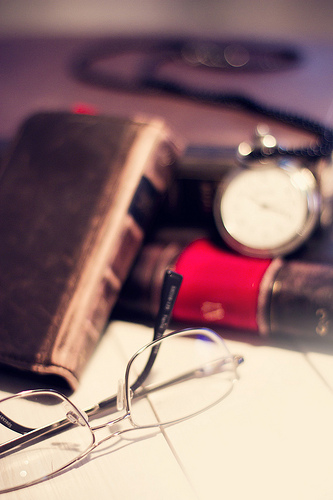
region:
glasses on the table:
[40, 244, 330, 479]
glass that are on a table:
[14, 269, 331, 452]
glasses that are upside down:
[10, 297, 318, 431]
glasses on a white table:
[14, 274, 325, 456]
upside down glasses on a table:
[6, 274, 300, 476]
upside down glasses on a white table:
[22, 260, 259, 489]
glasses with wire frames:
[10, 280, 302, 477]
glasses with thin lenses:
[26, 277, 284, 480]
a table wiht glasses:
[22, 235, 328, 466]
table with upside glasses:
[18, 259, 289, 490]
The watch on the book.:
[225, 161, 310, 249]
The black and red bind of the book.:
[133, 238, 331, 339]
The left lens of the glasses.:
[2, 387, 90, 475]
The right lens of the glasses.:
[113, 341, 228, 411]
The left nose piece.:
[62, 403, 85, 427]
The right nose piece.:
[107, 377, 127, 407]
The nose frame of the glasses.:
[97, 413, 131, 439]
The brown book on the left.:
[8, 99, 139, 353]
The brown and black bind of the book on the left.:
[42, 141, 165, 388]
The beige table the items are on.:
[20, 326, 318, 498]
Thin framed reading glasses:
[0, 272, 247, 491]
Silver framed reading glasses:
[0, 270, 246, 497]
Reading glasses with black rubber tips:
[0, 270, 247, 491]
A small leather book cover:
[3, 107, 187, 391]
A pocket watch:
[210, 155, 317, 250]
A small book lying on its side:
[117, 238, 327, 336]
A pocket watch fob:
[67, 33, 330, 158]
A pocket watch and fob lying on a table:
[70, 32, 328, 256]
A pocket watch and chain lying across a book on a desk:
[77, 30, 331, 258]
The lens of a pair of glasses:
[124, 329, 240, 423]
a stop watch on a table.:
[192, 121, 331, 264]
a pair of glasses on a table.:
[1, 300, 257, 497]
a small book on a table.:
[1, 104, 190, 421]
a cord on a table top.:
[67, 30, 331, 142]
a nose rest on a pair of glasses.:
[110, 375, 127, 416]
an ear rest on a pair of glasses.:
[94, 264, 188, 409]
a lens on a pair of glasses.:
[125, 320, 233, 427]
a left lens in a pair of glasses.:
[0, 380, 89, 494]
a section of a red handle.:
[137, 225, 293, 344]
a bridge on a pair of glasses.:
[92, 406, 131, 446]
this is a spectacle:
[86, 345, 202, 420]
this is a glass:
[150, 358, 206, 396]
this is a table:
[254, 377, 322, 471]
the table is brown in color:
[245, 435, 311, 479]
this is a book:
[30, 125, 116, 283]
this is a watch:
[226, 159, 302, 232]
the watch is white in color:
[237, 206, 257, 234]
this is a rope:
[256, 86, 325, 131]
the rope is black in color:
[285, 108, 324, 137]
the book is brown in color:
[36, 161, 77, 218]